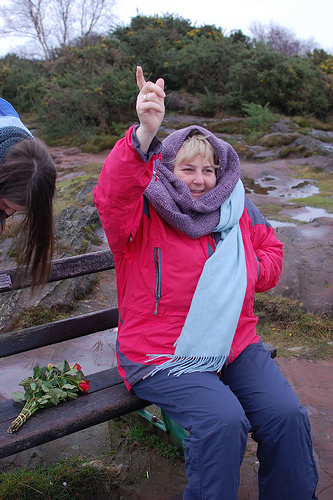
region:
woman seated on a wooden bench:
[1, 65, 317, 499]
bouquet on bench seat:
[6, 355, 87, 435]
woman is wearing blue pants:
[131, 337, 317, 498]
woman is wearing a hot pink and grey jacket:
[92, 122, 284, 390]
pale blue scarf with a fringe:
[141, 177, 243, 379]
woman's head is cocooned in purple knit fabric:
[145, 124, 241, 236]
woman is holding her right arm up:
[93, 63, 164, 248]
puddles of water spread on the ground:
[242, 166, 330, 230]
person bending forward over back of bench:
[0, 96, 58, 299]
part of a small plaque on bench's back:
[0, 270, 12, 289]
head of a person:
[159, 123, 233, 199]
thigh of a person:
[163, 365, 242, 429]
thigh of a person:
[232, 347, 306, 419]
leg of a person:
[189, 441, 243, 496]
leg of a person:
[258, 437, 326, 498]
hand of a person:
[123, 55, 174, 127]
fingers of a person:
[130, 64, 169, 108]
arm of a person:
[232, 192, 297, 294]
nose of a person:
[187, 173, 207, 185]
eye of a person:
[174, 155, 199, 175]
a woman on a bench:
[112, 77, 313, 489]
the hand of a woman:
[112, 62, 170, 144]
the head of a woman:
[159, 122, 230, 220]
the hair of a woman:
[183, 144, 220, 163]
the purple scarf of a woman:
[141, 164, 204, 230]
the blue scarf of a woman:
[195, 228, 267, 369]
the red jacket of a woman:
[79, 139, 282, 357]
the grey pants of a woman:
[128, 377, 331, 496]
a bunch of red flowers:
[14, 357, 85, 428]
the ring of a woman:
[133, 91, 155, 108]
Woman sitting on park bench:
[91, 64, 321, 498]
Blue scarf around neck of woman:
[140, 174, 247, 381]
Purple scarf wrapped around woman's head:
[140, 124, 243, 240]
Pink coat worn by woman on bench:
[91, 122, 285, 391]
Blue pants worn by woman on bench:
[129, 335, 320, 499]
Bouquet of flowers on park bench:
[5, 358, 91, 435]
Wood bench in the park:
[1, 247, 279, 460]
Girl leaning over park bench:
[0, 93, 60, 298]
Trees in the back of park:
[0, 0, 331, 151]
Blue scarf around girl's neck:
[0, 125, 36, 158]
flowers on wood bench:
[7, 358, 93, 436]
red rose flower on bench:
[78, 372, 92, 392]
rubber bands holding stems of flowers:
[11, 404, 33, 431]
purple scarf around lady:
[154, 129, 192, 217]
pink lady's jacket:
[96, 157, 282, 366]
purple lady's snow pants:
[146, 350, 320, 495]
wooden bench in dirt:
[0, 240, 137, 472]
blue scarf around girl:
[0, 124, 41, 153]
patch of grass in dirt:
[274, 306, 321, 344]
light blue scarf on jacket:
[157, 224, 249, 368]